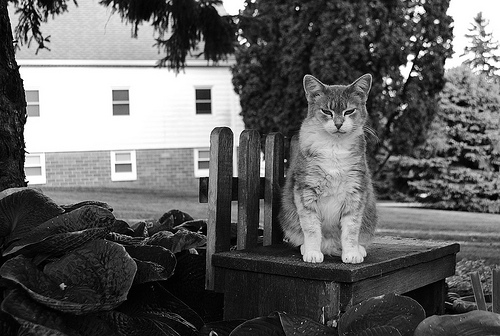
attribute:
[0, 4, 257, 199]
tree — evergreen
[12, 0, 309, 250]
house — two story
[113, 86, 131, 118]
window — exterior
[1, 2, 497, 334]
photo — black and white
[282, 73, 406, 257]
cat — white, gray, medium length haired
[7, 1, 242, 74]
branches — hanging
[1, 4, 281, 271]
building — back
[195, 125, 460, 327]
chair — wood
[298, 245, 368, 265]
paws — white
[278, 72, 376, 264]
cat — black and white, sitting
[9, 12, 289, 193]
building — white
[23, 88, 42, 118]
window — row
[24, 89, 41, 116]
window — multiple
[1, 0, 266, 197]
home — white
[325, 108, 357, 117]
eyes — cats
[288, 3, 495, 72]
trees — back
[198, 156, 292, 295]
object — wood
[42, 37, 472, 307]
photo — black, white